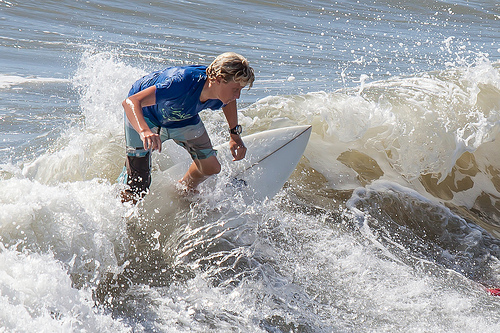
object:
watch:
[226, 124, 242, 137]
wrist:
[226, 127, 244, 142]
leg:
[114, 139, 153, 207]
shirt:
[125, 64, 230, 129]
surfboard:
[119, 124, 314, 216]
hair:
[203, 52, 258, 92]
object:
[483, 284, 499, 295]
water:
[258, 7, 367, 86]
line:
[227, 123, 311, 189]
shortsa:
[121, 113, 217, 161]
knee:
[190, 157, 223, 177]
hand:
[221, 136, 247, 161]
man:
[118, 51, 257, 207]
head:
[204, 50, 256, 105]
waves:
[24, 73, 484, 302]